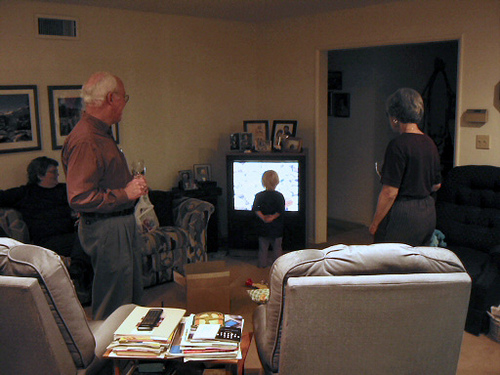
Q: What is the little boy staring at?
A: The television.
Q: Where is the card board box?
A: In the middle of the floor.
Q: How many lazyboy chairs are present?
A: Three.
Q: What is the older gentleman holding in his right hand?
A: A wine glass.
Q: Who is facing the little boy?
A: All three adults.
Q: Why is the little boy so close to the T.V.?
A: He is intrigued.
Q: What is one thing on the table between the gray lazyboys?
A: The remote control.